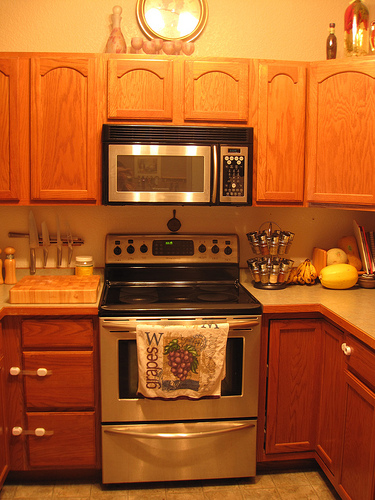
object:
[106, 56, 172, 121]
cabinet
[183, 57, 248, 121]
cabinet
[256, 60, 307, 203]
cabinet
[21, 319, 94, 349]
drawer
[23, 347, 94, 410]
drawer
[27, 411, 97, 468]
drawer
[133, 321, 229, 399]
towel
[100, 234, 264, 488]
stove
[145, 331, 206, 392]
design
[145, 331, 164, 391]
text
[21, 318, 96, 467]
door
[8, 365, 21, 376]
knob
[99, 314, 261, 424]
door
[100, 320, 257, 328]
handle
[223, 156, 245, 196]
display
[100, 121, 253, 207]
microwave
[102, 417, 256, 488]
broiler draw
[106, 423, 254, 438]
handle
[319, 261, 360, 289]
squash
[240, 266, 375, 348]
counter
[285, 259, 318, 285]
bananas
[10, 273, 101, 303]
chopping block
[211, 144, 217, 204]
handle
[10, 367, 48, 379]
safety lock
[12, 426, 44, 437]
safety lock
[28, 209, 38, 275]
knife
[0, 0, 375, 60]
wall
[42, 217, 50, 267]
knife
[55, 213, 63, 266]
knife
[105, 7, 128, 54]
decorative bottle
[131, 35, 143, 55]
decorative bottle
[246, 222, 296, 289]
rack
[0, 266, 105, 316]
counter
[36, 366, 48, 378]
knob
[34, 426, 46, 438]
knob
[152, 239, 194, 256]
digital clock